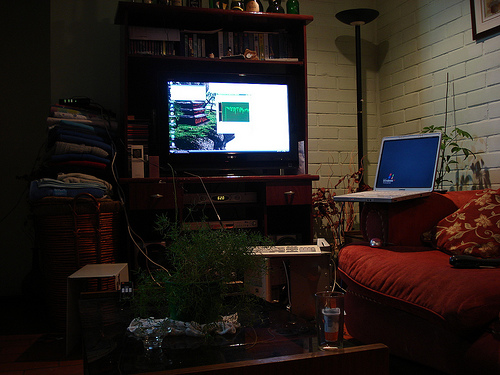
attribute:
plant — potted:
[127, 204, 274, 318]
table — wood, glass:
[79, 285, 390, 374]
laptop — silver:
[331, 133, 443, 203]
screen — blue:
[375, 136, 442, 187]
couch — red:
[339, 191, 499, 374]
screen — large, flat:
[169, 83, 290, 154]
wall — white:
[307, 2, 498, 232]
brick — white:
[261, 1, 499, 231]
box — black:
[56, 98, 91, 108]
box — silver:
[185, 194, 259, 204]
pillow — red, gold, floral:
[418, 190, 498, 258]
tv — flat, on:
[162, 75, 298, 168]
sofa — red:
[337, 189, 499, 374]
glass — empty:
[313, 292, 344, 350]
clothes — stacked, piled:
[30, 104, 117, 197]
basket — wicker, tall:
[42, 193, 116, 275]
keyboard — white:
[245, 244, 326, 256]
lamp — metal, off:
[334, 7, 379, 230]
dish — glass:
[271, 319, 307, 336]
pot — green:
[166, 282, 221, 323]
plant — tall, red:
[313, 157, 373, 291]